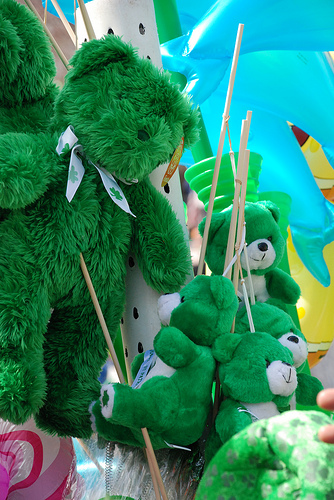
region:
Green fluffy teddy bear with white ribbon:
[16, 40, 186, 398]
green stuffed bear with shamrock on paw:
[91, 277, 240, 452]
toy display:
[19, 20, 300, 345]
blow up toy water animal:
[167, 5, 329, 113]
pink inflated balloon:
[6, 407, 91, 495]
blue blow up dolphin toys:
[174, 13, 333, 284]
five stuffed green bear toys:
[7, 78, 329, 432]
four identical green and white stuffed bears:
[103, 212, 329, 470]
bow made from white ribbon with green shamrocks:
[22, 122, 141, 224]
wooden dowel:
[196, 21, 264, 280]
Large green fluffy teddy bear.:
[0, 36, 201, 439]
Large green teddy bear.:
[88, 268, 246, 455]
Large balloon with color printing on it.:
[0, 428, 93, 496]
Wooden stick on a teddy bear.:
[71, 252, 185, 499]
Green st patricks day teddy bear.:
[212, 330, 304, 444]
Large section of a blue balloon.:
[162, 0, 331, 242]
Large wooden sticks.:
[224, 100, 256, 301]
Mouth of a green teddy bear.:
[255, 353, 297, 398]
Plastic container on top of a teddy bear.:
[182, 147, 273, 224]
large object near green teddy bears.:
[68, 0, 172, 85]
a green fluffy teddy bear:
[0, 35, 189, 441]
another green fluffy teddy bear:
[211, 337, 304, 414]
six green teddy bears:
[0, 1, 312, 402]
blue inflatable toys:
[160, 1, 329, 94]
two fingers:
[312, 386, 332, 440]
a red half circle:
[0, 428, 42, 490]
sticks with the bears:
[191, 17, 249, 277]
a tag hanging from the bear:
[159, 133, 192, 187]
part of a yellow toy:
[303, 282, 331, 337]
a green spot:
[129, 304, 143, 322]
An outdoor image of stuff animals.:
[7, 3, 332, 492]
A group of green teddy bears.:
[9, 3, 300, 489]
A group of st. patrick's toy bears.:
[7, 10, 292, 482]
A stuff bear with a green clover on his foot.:
[84, 265, 233, 456]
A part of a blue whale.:
[162, 5, 332, 123]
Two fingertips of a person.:
[306, 375, 332, 439]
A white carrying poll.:
[60, 3, 213, 498]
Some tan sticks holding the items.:
[206, 18, 267, 323]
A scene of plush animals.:
[10, 7, 332, 496]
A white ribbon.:
[45, 118, 142, 229]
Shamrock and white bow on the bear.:
[55, 121, 136, 220]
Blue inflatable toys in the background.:
[155, 2, 331, 252]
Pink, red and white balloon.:
[2, 414, 73, 498]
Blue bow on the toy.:
[130, 346, 161, 388]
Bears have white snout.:
[153, 233, 318, 395]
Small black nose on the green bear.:
[134, 119, 155, 146]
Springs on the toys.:
[97, 440, 178, 497]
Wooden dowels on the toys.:
[69, 100, 288, 497]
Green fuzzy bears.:
[2, 5, 205, 442]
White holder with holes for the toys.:
[65, 0, 188, 406]